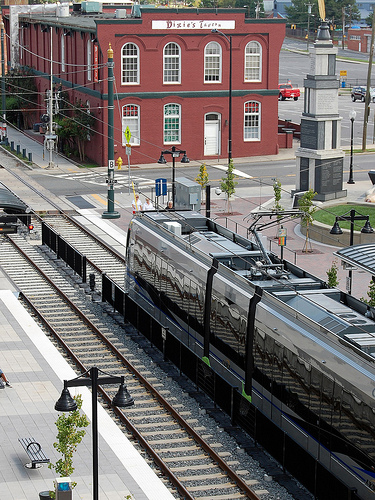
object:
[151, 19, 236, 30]
white sign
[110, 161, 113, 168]
b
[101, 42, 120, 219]
post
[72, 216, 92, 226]
floor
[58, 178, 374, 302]
sidewalk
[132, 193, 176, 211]
people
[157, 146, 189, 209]
street light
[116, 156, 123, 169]
hydrants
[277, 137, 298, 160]
ground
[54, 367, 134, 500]
light post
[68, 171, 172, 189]
crosswalk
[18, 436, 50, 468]
bench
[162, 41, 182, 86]
window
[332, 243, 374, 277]
roof shelter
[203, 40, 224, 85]
window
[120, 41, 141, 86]
window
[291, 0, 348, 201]
statue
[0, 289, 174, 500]
platform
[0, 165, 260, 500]
train tracks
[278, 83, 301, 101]
truck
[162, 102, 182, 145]
window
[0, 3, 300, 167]
building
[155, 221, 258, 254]
train engine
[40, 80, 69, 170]
signal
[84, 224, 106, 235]
floor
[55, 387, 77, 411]
lanterns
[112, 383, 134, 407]
lanterns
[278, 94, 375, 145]
parking lot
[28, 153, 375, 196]
street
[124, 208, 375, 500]
train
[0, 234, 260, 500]
tracks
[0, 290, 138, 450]
ground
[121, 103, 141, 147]
windows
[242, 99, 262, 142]
windows